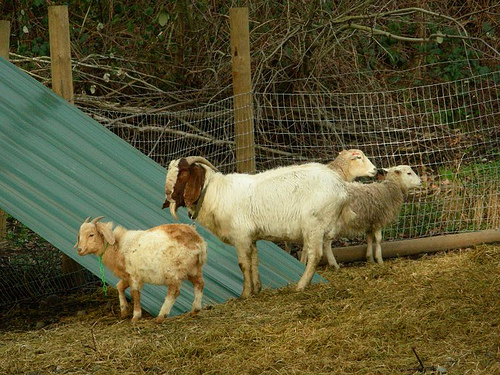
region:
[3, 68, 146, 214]
Blue aluminum sheet leaning on fence.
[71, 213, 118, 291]
Baby goat wearing a green chain.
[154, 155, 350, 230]
An older goat with horns.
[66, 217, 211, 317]
A tan and off-white baby goat.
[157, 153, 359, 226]
A white and brown adult goat.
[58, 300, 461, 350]
Well groomed grass.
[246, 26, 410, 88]
Shurbs behind the fence.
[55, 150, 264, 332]
Two goats next to blue aluminum sheet.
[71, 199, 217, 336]
this is a goat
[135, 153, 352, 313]
this is a goat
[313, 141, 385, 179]
this is a goat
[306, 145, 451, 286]
this is a goat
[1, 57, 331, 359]
this is a iron sheet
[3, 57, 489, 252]
this is a fence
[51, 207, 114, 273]
the head of a goat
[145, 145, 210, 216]
the head of a goat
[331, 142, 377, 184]
the head of a goat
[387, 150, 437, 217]
the head of a goat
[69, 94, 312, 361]
The sheep are white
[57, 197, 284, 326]
The goat has horns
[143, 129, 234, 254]
The goat has a brown and white face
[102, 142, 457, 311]
Four goats are pictured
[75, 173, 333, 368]
The goats are next to a green fence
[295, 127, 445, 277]
The goats are next to a wired fence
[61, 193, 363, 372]
The goat has a green collar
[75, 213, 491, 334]
The goat is standing on dead grass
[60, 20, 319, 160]
Trees are behind the fence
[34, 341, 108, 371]
Part of green grass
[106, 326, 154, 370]
Part of green grass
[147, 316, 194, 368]
Part of green grass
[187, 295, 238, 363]
Part of green grass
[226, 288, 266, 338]
Part of green grass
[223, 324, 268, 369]
Part of green grass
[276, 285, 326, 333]
Part of green grass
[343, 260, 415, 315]
Part of green grass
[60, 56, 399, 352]
White sheeps in a field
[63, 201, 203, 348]
Small white and brown sheep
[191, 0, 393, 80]
old tree branches in the back ground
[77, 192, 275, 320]
a little baby goat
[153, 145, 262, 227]
the head of a got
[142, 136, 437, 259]
a white and brown goat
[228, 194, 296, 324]
front legs of a goat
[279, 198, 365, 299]
back legs of a goat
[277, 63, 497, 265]
goats near a fence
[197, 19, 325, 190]
a wood pole holding up a fence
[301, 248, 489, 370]
a grassy area in a goat pen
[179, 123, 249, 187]
a horn of a goat